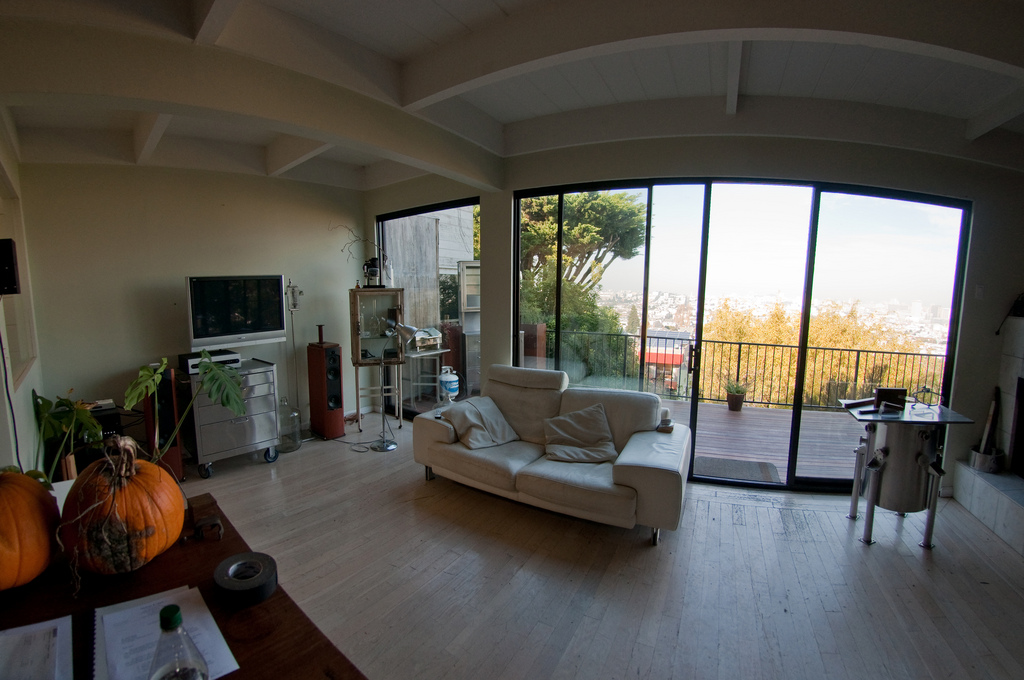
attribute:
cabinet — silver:
[187, 351, 286, 465]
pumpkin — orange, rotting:
[62, 433, 187, 577]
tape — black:
[194, 526, 281, 596]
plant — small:
[713, 350, 752, 421]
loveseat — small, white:
[396, 347, 707, 560]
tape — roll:
[207, 533, 297, 597]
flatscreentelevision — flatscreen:
[162, 251, 308, 353]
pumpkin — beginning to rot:
[51, 415, 216, 578]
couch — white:
[416, 356, 691, 563]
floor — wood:
[124, 410, 1022, 677]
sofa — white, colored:
[399, 350, 690, 548]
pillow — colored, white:
[425, 385, 512, 447]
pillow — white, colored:
[552, 411, 606, 453]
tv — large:
[198, 268, 260, 351]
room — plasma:
[8, 128, 1014, 678]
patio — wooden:
[445, 331, 936, 450]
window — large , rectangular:
[795, 185, 936, 484]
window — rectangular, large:
[698, 213, 823, 483]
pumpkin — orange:
[73, 458, 179, 575]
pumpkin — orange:
[0, 458, 65, 599]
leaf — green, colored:
[201, 354, 271, 411]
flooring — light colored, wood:
[202, 404, 1013, 675]